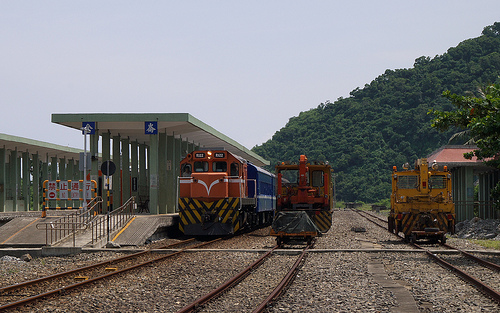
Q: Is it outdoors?
A: Yes, it is outdoors.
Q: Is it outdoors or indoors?
A: It is outdoors.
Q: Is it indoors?
A: No, it is outdoors.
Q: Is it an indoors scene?
A: No, it is outdoors.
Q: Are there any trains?
A: Yes, there is a train.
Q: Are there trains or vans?
A: Yes, there is a train.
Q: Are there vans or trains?
A: Yes, there is a train.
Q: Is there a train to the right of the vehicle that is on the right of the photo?
A: No, the train is to the left of the vehicle.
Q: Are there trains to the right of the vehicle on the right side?
A: No, the train is to the left of the vehicle.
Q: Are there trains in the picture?
A: Yes, there are trains.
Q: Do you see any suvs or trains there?
A: Yes, there are trains.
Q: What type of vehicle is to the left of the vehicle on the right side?
A: The vehicles are trains.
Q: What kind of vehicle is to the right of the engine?
A: The vehicles are trains.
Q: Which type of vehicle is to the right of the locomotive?
A: The vehicles are trains.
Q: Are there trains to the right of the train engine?
A: Yes, there are trains to the right of the train engine.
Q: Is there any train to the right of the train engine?
A: Yes, there are trains to the right of the train engine.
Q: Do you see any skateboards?
A: No, there are no skateboards.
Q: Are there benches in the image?
A: No, there are no benches.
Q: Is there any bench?
A: No, there are no benches.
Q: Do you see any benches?
A: No, there are no benches.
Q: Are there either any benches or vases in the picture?
A: No, there are no benches or vases.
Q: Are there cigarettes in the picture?
A: No, there are no cigarettes.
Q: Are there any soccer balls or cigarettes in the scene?
A: No, there are no cigarettes or soccer balls.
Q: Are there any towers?
A: No, there are no towers.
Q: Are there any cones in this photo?
A: No, there are no cones.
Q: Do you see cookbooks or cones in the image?
A: No, there are no cones or cookbooks.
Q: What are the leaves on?
A: The leaves are on the tree.